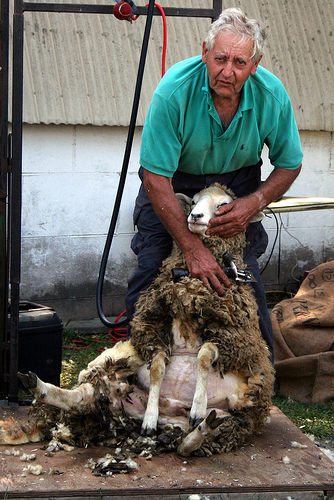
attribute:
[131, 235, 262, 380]
fur — matted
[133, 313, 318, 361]
wool — dirty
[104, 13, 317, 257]
man — old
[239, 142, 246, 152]
blue emblem — dark blue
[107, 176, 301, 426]
sheep — complacent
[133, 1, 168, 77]
wire — red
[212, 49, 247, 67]
eyes — open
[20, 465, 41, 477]
sheep wool — dirty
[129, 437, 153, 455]
sheep wool — dirty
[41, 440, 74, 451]
sheep wool — dirty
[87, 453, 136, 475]
sheep wool — dirty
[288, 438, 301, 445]
sheep wool — dirty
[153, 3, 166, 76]
wire — thin, red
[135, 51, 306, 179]
shirt — light blue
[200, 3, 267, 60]
hair — gray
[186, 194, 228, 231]
face — white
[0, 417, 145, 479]
hair — shaved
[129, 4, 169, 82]
hose — red